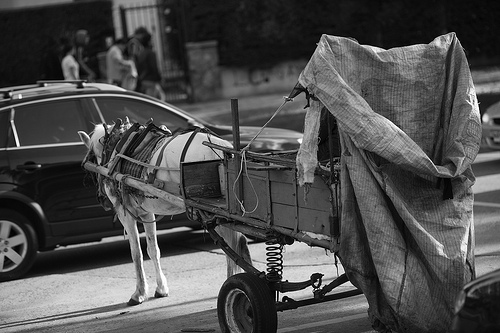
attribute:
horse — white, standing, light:
[65, 103, 249, 258]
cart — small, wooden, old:
[217, 80, 444, 281]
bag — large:
[317, 64, 492, 284]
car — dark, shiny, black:
[16, 77, 319, 255]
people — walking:
[59, 24, 154, 89]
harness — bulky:
[104, 134, 169, 175]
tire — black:
[193, 263, 282, 333]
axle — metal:
[269, 282, 385, 315]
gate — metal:
[111, 9, 193, 88]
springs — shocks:
[252, 224, 317, 294]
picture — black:
[33, 36, 483, 319]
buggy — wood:
[235, 122, 424, 258]